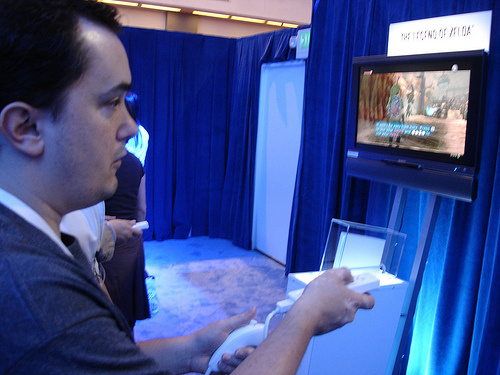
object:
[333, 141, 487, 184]
sensor bar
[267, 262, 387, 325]
controller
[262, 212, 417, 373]
gaming system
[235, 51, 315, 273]
frame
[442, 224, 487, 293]
drapes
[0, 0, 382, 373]
guy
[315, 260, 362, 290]
thumb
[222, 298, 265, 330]
thumb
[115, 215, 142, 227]
thumb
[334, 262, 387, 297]
button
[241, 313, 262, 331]
button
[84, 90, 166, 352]
woman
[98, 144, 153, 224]
back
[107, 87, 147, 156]
hair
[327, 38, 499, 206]
flat screen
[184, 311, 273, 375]
nunchuck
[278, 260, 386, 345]
hand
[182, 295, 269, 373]
hand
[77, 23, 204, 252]
drapes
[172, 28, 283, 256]
curtain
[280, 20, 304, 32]
light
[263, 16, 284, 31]
light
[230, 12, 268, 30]
light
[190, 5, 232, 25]
light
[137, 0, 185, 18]
light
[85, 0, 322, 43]
ceiling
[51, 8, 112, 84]
hair line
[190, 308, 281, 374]
game controller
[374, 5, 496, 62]
sign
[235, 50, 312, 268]
door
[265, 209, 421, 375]
wii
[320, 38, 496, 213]
television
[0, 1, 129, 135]
hair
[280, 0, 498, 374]
curtain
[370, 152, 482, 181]
buttons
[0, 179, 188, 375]
shirt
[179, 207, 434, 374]
game